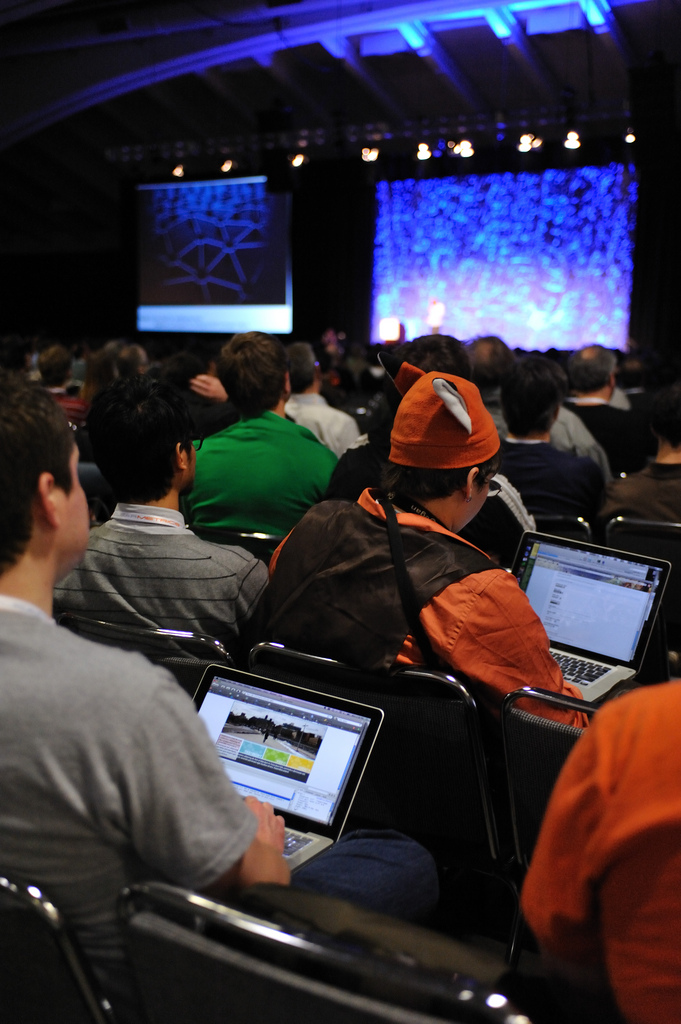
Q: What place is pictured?
A: It is a theater.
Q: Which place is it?
A: It is a theater.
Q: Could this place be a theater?
A: Yes, it is a theater.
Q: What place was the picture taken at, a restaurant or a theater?
A: It was taken at a theater.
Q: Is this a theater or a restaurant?
A: It is a theater.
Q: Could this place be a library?
A: No, it is a theater.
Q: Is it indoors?
A: Yes, it is indoors.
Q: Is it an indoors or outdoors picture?
A: It is indoors.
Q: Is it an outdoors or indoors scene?
A: It is indoors.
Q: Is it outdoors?
A: No, it is indoors.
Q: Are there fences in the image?
A: No, there are no fences.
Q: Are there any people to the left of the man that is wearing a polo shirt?
A: Yes, there is a person to the left of the man.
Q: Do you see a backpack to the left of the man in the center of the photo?
A: No, there is a person to the left of the man.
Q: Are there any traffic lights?
A: No, there are no traffic lights.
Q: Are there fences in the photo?
A: No, there are no fences.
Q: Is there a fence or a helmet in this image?
A: No, there are no fences or helmets.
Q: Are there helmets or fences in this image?
A: No, there are no fences or helmets.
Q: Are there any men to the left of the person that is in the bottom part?
A: Yes, there is a man to the left of the person.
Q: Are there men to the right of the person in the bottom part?
A: No, the man is to the left of the person.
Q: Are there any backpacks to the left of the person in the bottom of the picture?
A: No, there is a man to the left of the person.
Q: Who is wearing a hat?
A: The man is wearing a hat.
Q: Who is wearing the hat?
A: The man is wearing a hat.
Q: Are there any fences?
A: No, there are no fences.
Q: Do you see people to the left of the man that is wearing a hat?
A: Yes, there is a person to the left of the man.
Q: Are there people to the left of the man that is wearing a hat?
A: Yes, there is a person to the left of the man.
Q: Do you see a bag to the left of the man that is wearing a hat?
A: No, there is a person to the left of the man.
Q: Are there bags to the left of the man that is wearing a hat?
A: No, there is a person to the left of the man.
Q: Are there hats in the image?
A: Yes, there is a hat.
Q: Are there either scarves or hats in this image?
A: Yes, there is a hat.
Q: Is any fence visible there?
A: No, there are no fences.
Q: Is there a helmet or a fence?
A: No, there are no fences or helmets.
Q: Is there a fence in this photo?
A: No, there are no fences.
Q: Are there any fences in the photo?
A: No, there are no fences.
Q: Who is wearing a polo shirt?
A: The man is wearing a polo shirt.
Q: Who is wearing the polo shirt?
A: The man is wearing a polo shirt.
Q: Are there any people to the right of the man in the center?
A: Yes, there is a person to the right of the man.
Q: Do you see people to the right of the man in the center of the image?
A: Yes, there is a person to the right of the man.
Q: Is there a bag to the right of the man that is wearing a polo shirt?
A: No, there is a person to the right of the man.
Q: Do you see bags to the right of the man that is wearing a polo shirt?
A: No, there is a person to the right of the man.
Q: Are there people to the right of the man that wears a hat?
A: Yes, there is a person to the right of the man.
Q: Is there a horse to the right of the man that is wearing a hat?
A: No, there is a person to the right of the man.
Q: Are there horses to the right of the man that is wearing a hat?
A: No, there is a person to the right of the man.